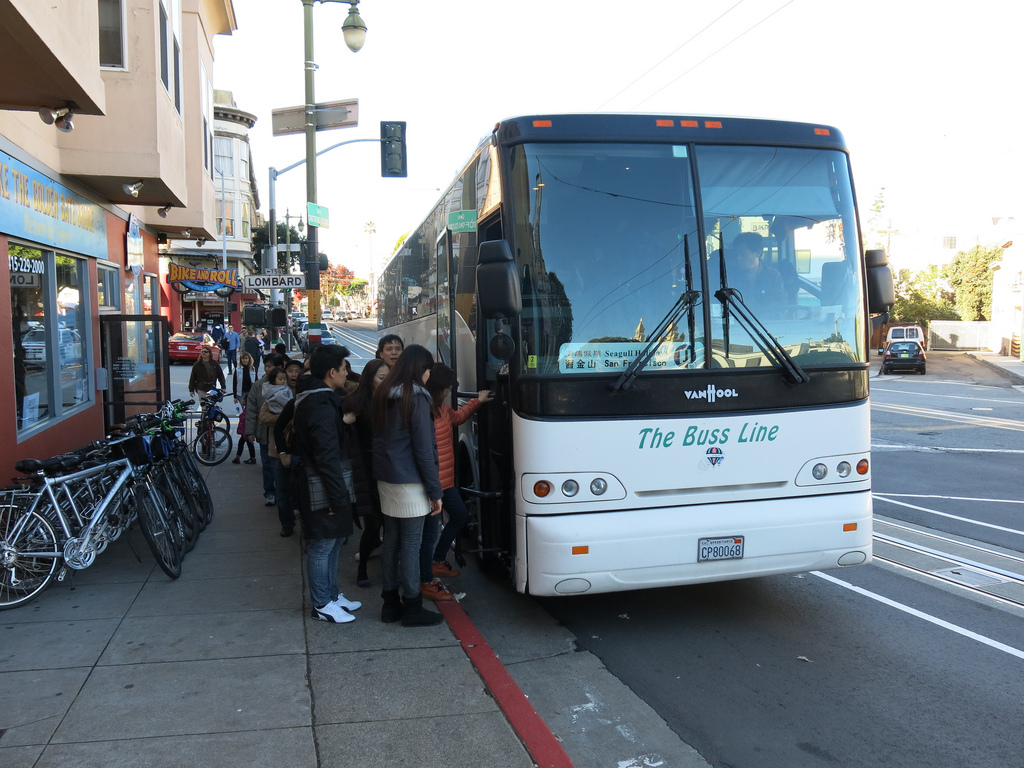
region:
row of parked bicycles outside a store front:
[1, 395, 218, 608]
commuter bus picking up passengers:
[371, 111, 875, 601]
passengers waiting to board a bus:
[245, 335, 493, 633]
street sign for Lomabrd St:
[242, 271, 304, 294]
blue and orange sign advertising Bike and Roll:
[162, 260, 240, 292]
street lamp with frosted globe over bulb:
[339, 4, 369, 53]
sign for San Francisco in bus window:
[554, 338, 709, 374]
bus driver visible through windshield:
[716, 228, 792, 324]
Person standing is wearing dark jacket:
[376, 337, 446, 632]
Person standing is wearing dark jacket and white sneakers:
[278, 337, 377, 623]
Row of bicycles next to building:
[7, 377, 208, 611]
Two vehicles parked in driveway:
[883, 323, 931, 377]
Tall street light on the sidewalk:
[298, 0, 372, 346]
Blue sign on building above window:
[0, 153, 112, 261]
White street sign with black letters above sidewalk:
[242, 270, 310, 293]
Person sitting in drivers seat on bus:
[718, 226, 780, 334]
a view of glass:
[465, 82, 865, 389]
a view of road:
[691, 638, 863, 763]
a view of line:
[438, 667, 565, 760]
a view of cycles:
[24, 320, 220, 609]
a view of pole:
[246, 161, 383, 326]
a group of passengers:
[255, 335, 540, 671]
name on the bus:
[632, 421, 911, 488]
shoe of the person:
[307, 590, 413, 664]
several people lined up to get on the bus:
[245, 284, 473, 639]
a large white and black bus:
[354, 95, 898, 611]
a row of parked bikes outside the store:
[9, 376, 226, 601]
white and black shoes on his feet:
[294, 593, 362, 635]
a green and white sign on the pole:
[300, 195, 338, 237]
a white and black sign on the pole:
[243, 266, 317, 298]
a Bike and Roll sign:
[168, 256, 241, 301]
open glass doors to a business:
[100, 298, 177, 451]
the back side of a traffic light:
[376, 114, 408, 185]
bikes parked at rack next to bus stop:
[0, 390, 208, 613]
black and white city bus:
[383, 117, 906, 618]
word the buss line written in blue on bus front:
[636, 420, 793, 452]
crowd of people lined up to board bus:
[251, 322, 487, 629]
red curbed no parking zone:
[438, 589, 576, 766]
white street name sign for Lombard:
[238, 266, 312, 298]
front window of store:
[13, 250, 100, 434]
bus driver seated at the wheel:
[702, 228, 819, 334]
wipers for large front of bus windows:
[615, 238, 816, 393]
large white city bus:
[355, 111, 907, 634]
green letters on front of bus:
[631, 417, 787, 465]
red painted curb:
[428, 569, 572, 766]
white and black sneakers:
[315, 581, 361, 632]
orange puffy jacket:
[437, 363, 476, 497]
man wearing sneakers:
[260, 331, 378, 617]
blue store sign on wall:
[1, 158, 129, 266]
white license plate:
[689, 531, 750, 570]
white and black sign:
[239, 268, 313, 289]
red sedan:
[166, 319, 227, 371]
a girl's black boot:
[399, 591, 445, 629]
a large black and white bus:
[380, 108, 884, 593]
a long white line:
[822, 571, 1022, 674]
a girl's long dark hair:
[378, 342, 437, 442]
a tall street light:
[302, 0, 367, 354]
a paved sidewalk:
[2, 404, 538, 765]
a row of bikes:
[0, 383, 220, 608]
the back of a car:
[882, 341, 927, 373]